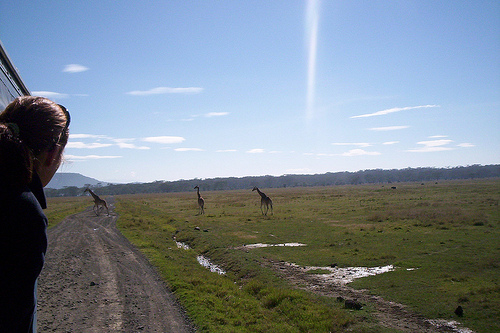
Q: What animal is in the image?
A: Giraffe.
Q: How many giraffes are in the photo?
A: 3.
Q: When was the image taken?
A: Daytime.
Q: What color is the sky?
A: Blue.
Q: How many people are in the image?
A: 1.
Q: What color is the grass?
A: Green.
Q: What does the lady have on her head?
A: Sunglasses.